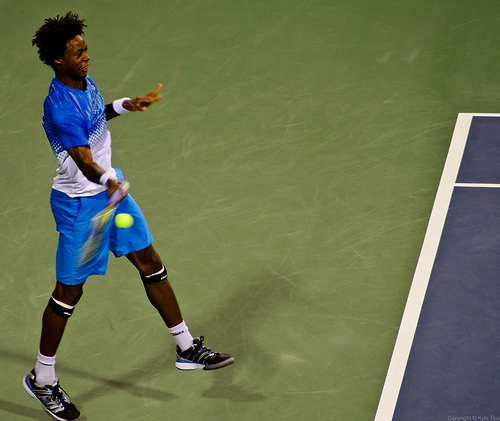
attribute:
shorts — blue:
[44, 165, 159, 289]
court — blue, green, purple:
[2, 1, 494, 420]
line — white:
[374, 97, 480, 420]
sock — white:
[164, 317, 193, 349]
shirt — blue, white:
[35, 71, 129, 198]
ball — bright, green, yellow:
[112, 207, 135, 231]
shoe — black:
[172, 336, 236, 373]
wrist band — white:
[108, 92, 134, 116]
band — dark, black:
[140, 264, 167, 285]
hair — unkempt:
[27, 10, 87, 66]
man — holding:
[22, 15, 237, 381]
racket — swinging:
[73, 176, 136, 282]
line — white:
[437, 178, 498, 188]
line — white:
[451, 110, 496, 120]